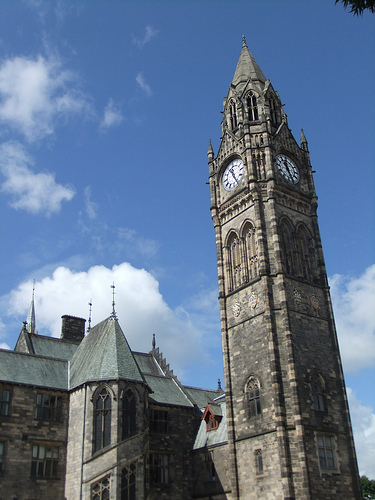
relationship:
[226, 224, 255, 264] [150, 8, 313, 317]
window on tower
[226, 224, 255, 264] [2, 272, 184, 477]
window on church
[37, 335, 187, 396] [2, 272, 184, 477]
roof of church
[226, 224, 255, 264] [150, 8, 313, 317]
window in tower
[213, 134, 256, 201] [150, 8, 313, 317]
clock on tower